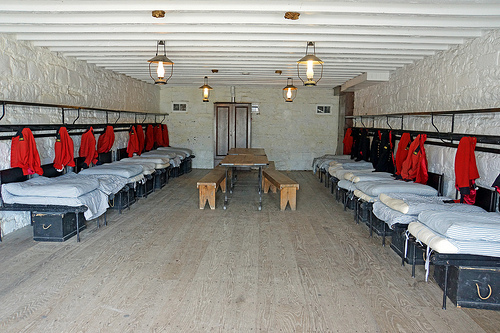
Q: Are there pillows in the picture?
A: Yes, there is a pillow.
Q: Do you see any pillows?
A: Yes, there is a pillow.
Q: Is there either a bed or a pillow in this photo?
A: Yes, there is a pillow.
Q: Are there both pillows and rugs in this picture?
A: No, there is a pillow but no rugs.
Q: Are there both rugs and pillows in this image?
A: No, there is a pillow but no rugs.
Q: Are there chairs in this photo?
A: No, there are no chairs.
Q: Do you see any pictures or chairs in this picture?
A: No, there are no chairs or pictures.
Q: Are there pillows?
A: Yes, there is a pillow.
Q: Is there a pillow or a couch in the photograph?
A: Yes, there is a pillow.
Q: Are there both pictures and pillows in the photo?
A: No, there is a pillow but no pictures.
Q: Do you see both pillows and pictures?
A: No, there is a pillow but no pictures.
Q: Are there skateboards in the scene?
A: No, there are no skateboards.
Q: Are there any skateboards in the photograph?
A: No, there are no skateboards.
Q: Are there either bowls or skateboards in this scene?
A: No, there are no skateboards or bowls.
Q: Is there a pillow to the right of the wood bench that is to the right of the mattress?
A: Yes, there is a pillow to the right of the bench.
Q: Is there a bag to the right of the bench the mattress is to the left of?
A: No, there is a pillow to the right of the bench.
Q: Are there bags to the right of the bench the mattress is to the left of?
A: No, there is a pillow to the right of the bench.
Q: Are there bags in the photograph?
A: No, there are no bags.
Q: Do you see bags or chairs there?
A: No, there are no bags or chairs.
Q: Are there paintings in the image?
A: No, there are no paintings.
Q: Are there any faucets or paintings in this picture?
A: No, there are no paintings or faucets.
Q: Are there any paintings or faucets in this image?
A: No, there are no paintings or faucets.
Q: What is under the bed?
A: The trunks are under the bed.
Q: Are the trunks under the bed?
A: Yes, the trunks are under the bed.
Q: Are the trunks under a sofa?
A: No, the trunks are under the bed.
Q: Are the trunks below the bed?
A: Yes, the trunks are below the bed.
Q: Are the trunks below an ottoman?
A: No, the trunks are below the bed.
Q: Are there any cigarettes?
A: No, there are no cigarettes.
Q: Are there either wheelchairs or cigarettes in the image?
A: No, there are no cigarettes or wheelchairs.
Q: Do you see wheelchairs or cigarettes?
A: No, there are no cigarettes or wheelchairs.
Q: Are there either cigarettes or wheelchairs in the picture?
A: No, there are no cigarettes or wheelchairs.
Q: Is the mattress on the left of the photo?
A: Yes, the mattress is on the left of the image.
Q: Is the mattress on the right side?
A: No, the mattress is on the left of the image.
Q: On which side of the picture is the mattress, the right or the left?
A: The mattress is on the left of the image.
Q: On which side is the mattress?
A: The mattress is on the left of the image.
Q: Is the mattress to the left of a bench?
A: Yes, the mattress is to the left of a bench.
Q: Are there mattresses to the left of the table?
A: Yes, there is a mattress to the left of the table.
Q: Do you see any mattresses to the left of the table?
A: Yes, there is a mattress to the left of the table.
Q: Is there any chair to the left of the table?
A: No, there is a mattress to the left of the table.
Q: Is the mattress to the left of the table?
A: Yes, the mattress is to the left of the table.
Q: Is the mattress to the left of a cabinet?
A: No, the mattress is to the left of the table.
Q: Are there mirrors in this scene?
A: No, there are no mirrors.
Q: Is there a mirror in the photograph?
A: No, there are no mirrors.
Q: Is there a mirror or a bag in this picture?
A: No, there are no mirrors or bags.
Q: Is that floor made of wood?
A: Yes, the floor is made of wood.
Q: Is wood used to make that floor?
A: Yes, the floor is made of wood.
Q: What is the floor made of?
A: The floor is made of wood.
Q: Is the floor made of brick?
A: No, the floor is made of wood.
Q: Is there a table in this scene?
A: Yes, there is a table.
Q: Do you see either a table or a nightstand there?
A: Yes, there is a table.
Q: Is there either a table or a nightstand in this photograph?
A: Yes, there is a table.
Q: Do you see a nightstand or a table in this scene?
A: Yes, there is a table.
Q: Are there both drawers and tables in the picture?
A: No, there is a table but no drawers.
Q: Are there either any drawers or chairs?
A: No, there are no chairs or drawers.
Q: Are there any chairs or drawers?
A: No, there are no chairs or drawers.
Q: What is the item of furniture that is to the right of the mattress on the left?
A: The piece of furniture is a table.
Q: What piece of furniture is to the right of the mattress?
A: The piece of furniture is a table.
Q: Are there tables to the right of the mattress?
A: Yes, there is a table to the right of the mattress.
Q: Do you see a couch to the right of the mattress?
A: No, there is a table to the right of the mattress.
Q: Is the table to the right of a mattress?
A: Yes, the table is to the right of a mattress.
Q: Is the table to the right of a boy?
A: No, the table is to the right of a mattress.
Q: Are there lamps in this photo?
A: Yes, there is a lamp.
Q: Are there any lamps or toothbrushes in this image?
A: Yes, there is a lamp.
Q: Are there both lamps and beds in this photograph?
A: Yes, there are both a lamp and a bed.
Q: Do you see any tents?
A: No, there are no tents.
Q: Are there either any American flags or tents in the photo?
A: No, there are no tents or American flags.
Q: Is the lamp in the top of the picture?
A: Yes, the lamp is in the top of the image.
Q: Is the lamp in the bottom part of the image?
A: No, the lamp is in the top of the image.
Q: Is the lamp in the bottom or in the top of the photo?
A: The lamp is in the top of the image.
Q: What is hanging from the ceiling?
A: The lamp is hanging from the ceiling.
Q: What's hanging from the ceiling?
A: The lamp is hanging from the ceiling.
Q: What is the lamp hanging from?
A: The lamp is hanging from the ceiling.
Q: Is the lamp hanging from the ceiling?
A: Yes, the lamp is hanging from the ceiling.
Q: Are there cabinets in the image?
A: No, there are no cabinets.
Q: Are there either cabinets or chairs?
A: No, there are no cabinets or chairs.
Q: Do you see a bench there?
A: Yes, there is a bench.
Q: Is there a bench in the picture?
A: Yes, there is a bench.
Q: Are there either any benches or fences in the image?
A: Yes, there is a bench.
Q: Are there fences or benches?
A: Yes, there is a bench.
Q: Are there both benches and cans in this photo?
A: No, there is a bench but no cans.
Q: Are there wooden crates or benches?
A: Yes, there is a wood bench.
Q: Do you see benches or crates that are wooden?
A: Yes, the bench is wooden.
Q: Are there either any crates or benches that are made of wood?
A: Yes, the bench is made of wood.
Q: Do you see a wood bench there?
A: Yes, there is a wood bench.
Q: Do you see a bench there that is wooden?
A: Yes, there is a bench that is wooden.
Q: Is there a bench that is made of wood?
A: Yes, there is a bench that is made of wood.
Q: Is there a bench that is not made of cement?
A: Yes, there is a bench that is made of wood.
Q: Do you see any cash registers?
A: No, there are no cash registers.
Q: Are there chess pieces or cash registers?
A: No, there are no cash registers or chess pieces.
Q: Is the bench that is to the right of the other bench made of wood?
A: Yes, the bench is made of wood.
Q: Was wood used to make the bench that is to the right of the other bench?
A: Yes, the bench is made of wood.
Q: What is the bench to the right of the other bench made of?
A: The bench is made of wood.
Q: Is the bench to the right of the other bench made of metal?
A: No, the bench is made of wood.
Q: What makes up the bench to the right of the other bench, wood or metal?
A: The bench is made of wood.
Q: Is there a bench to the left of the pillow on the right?
A: Yes, there is a bench to the left of the pillow.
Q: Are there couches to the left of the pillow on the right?
A: No, there is a bench to the left of the pillow.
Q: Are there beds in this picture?
A: Yes, there is a bed.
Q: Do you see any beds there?
A: Yes, there is a bed.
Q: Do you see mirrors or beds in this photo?
A: Yes, there is a bed.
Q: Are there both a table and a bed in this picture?
A: Yes, there are both a bed and a table.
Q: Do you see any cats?
A: No, there are no cats.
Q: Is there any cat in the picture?
A: No, there are no cats.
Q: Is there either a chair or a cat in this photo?
A: No, there are no cats or chairs.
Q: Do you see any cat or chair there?
A: No, there are no cats or chairs.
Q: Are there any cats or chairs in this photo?
A: No, there are no cats or chairs.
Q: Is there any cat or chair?
A: No, there are no cats or chairs.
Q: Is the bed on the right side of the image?
A: Yes, the bed is on the right of the image.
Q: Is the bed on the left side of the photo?
A: No, the bed is on the right of the image.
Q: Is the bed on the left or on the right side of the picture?
A: The bed is on the right of the image.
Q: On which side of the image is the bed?
A: The bed is on the right of the image.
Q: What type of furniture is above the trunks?
A: The piece of furniture is a bed.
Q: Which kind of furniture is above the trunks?
A: The piece of furniture is a bed.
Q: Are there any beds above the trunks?
A: Yes, there is a bed above the trunks.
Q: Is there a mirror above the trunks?
A: No, there is a bed above the trunks.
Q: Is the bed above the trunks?
A: Yes, the bed is above the trunks.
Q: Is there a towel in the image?
A: No, there are no towels.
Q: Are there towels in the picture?
A: No, there are no towels.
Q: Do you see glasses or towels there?
A: No, there are no towels or glasses.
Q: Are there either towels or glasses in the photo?
A: No, there are no towels or glasses.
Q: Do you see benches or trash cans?
A: Yes, there is a bench.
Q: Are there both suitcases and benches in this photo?
A: No, there is a bench but no suitcases.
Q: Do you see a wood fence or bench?
A: Yes, there is a wood bench.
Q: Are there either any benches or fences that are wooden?
A: Yes, the bench is wooden.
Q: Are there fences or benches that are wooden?
A: Yes, the bench is wooden.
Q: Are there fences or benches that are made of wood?
A: Yes, the bench is made of wood.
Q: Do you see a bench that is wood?
A: Yes, there is a wood bench.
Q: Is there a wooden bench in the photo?
A: Yes, there is a wood bench.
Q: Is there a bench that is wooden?
A: Yes, there is a bench that is wooden.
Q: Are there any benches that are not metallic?
A: Yes, there is a wooden bench.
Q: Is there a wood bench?
A: Yes, there is a bench that is made of wood.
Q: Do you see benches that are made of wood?
A: Yes, there is a bench that is made of wood.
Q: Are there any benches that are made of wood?
A: Yes, there is a bench that is made of wood.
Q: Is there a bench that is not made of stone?
A: Yes, there is a bench that is made of wood.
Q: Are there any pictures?
A: No, there are no pictures.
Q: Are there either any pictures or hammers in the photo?
A: No, there are no pictures or hammers.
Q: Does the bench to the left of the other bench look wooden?
A: Yes, the bench is wooden.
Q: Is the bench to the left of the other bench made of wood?
A: Yes, the bench is made of wood.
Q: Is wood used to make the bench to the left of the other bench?
A: Yes, the bench is made of wood.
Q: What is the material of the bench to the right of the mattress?
A: The bench is made of wood.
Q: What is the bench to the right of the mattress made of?
A: The bench is made of wood.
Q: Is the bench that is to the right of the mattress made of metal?
A: No, the bench is made of wood.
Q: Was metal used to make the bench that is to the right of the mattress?
A: No, the bench is made of wood.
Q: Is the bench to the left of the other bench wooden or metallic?
A: The bench is wooden.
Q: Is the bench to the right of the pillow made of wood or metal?
A: The bench is made of wood.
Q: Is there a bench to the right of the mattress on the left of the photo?
A: Yes, there is a bench to the right of the mattress.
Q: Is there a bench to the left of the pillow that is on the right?
A: Yes, there is a bench to the left of the pillow.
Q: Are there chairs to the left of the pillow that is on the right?
A: No, there is a bench to the left of the pillow.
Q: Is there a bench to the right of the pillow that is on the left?
A: Yes, there is a bench to the right of the pillow.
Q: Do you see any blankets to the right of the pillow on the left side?
A: No, there is a bench to the right of the pillow.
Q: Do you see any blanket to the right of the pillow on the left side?
A: No, there is a bench to the right of the pillow.